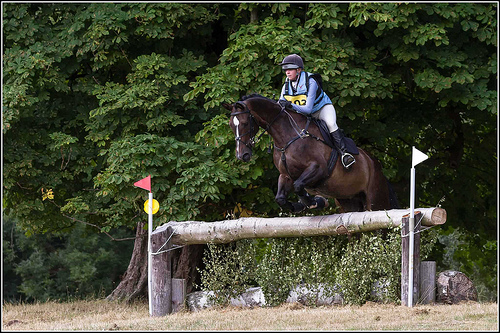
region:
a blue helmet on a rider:
[283, 52, 305, 71]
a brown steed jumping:
[225, 97, 371, 212]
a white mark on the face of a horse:
[228, 112, 241, 144]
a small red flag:
[134, 177, 153, 192]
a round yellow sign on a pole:
[143, 188, 157, 310]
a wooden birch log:
[157, 209, 440, 237]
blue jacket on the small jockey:
[283, 73, 328, 115]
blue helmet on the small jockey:
[282, 49, 307, 73]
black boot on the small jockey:
[329, 128, 354, 165]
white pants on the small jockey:
[310, 101, 339, 135]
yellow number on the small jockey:
[283, 93, 310, 110]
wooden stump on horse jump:
[147, 226, 170, 311]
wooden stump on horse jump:
[167, 245, 192, 311]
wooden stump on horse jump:
[395, 210, 417, 307]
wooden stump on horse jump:
[413, 254, 437, 304]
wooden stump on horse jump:
[158, 205, 447, 236]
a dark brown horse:
[225, 91, 394, 214]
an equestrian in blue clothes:
[276, 54, 357, 170]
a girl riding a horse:
[274, 51, 356, 170]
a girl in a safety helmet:
[275, 53, 358, 170]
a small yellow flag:
[406, 142, 430, 315]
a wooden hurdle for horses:
[142, 203, 451, 320]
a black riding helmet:
[277, 52, 307, 74]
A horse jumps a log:
[146, 95, 448, 317]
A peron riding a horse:
[230, 53, 391, 213]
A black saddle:
[313, 116, 358, 156]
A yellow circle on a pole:
[143, 199, 160, 214]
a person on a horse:
[222, 53, 390, 212]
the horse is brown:
[220, 93, 390, 211]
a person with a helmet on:
[275, 52, 355, 168]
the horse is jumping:
[218, 93, 390, 210]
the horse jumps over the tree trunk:
[150, 92, 447, 245]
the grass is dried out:
[0, 292, 498, 332]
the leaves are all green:
[0, 0, 497, 232]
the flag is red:
[132, 175, 153, 192]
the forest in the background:
[3, 6, 495, 300]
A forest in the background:
[4, 5, 484, 289]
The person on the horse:
[271, 47, 381, 161]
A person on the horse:
[270, 50, 370, 159]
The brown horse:
[221, 97, 381, 217]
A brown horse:
[224, 86, 395, 233]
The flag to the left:
[125, 166, 158, 192]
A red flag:
[128, 165, 165, 200]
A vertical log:
[159, 199, 446, 246]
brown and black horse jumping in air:
[223, 91, 385, 216]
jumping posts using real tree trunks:
[140, 206, 449, 319]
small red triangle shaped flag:
[132, 174, 152, 194]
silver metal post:
[146, 192, 153, 319]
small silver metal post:
[407, 167, 414, 308]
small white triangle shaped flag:
[410, 146, 431, 166]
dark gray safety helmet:
[278, 54, 304, 71]